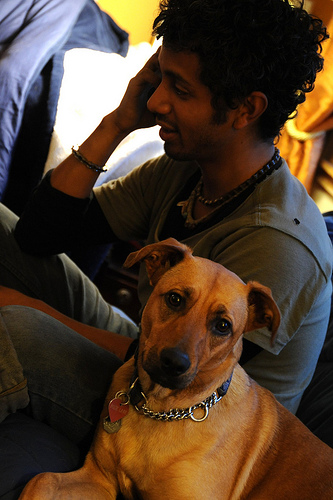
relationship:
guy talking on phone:
[1, 3, 331, 453] [138, 66, 161, 113]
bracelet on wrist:
[68, 145, 107, 174] [63, 148, 105, 171]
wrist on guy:
[63, 148, 105, 171] [1, 0, 333, 499]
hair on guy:
[233, 26, 298, 78] [1, 0, 333, 499]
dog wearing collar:
[78, 214, 330, 492] [128, 375, 232, 423]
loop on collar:
[187, 402, 209, 421] [128, 375, 232, 423]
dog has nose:
[19, 233, 333, 499] [39, 240, 332, 498]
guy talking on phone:
[1, 0, 333, 499] [143, 64, 159, 103]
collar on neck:
[102, 324, 234, 439] [138, 381, 215, 403]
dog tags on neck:
[100, 397, 128, 433] [126, 347, 234, 397]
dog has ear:
[19, 233, 333, 499] [240, 278, 288, 346]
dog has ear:
[19, 233, 333, 499] [111, 230, 194, 284]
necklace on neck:
[190, 151, 280, 206] [196, 140, 277, 195]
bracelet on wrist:
[68, 145, 107, 174] [63, 115, 135, 177]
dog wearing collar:
[19, 233, 333, 499] [102, 343, 231, 433]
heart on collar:
[106, 390, 131, 423] [127, 353, 234, 423]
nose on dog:
[159, 348, 190, 376] [19, 233, 333, 499]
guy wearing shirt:
[1, 0, 333, 499] [14, 137, 330, 420]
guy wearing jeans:
[1, 0, 333, 499] [1, 201, 140, 449]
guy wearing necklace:
[1, 0, 333, 499] [161, 150, 286, 221]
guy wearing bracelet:
[1, 0, 333, 499] [68, 145, 107, 174]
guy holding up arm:
[1, 0, 333, 499] [24, 44, 159, 262]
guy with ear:
[1, 0, 333, 499] [233, 88, 268, 130]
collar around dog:
[102, 324, 234, 439] [19, 233, 333, 499]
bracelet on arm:
[68, 145, 107, 174] [24, 44, 159, 262]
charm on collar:
[106, 396, 127, 421] [111, 334, 237, 421]